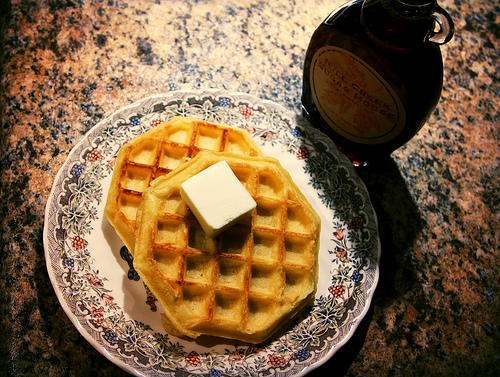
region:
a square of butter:
[182, 158, 254, 231]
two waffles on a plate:
[109, 118, 319, 345]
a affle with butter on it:
[138, 153, 317, 345]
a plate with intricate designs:
[45, 88, 379, 375]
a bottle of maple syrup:
[300, 1, 455, 166]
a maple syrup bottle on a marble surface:
[297, 4, 454, 157]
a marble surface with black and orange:
[3, 3, 496, 375]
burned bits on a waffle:
[115, 120, 226, 201]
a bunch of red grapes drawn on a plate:
[266, 351, 286, 366]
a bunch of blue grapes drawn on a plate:
[101, 325, 118, 346]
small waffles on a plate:
[37, 39, 439, 354]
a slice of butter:
[76, 109, 454, 375]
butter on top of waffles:
[46, 93, 468, 371]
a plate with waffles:
[30, 58, 452, 312]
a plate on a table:
[50, 64, 450, 351]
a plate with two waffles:
[54, 87, 307, 354]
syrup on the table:
[269, 16, 496, 218]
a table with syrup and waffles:
[2, 8, 492, 372]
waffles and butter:
[47, 81, 387, 361]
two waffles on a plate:
[107, 118, 329, 333]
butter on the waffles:
[178, 157, 261, 233]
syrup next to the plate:
[297, 1, 464, 155]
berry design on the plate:
[330, 212, 367, 303]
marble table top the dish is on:
[421, 183, 474, 290]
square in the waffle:
[212, 255, 249, 292]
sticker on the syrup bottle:
[303, 42, 411, 150]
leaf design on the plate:
[142, 326, 172, 360]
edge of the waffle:
[260, 155, 285, 175]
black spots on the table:
[122, 33, 170, 71]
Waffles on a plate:
[98, 116, 320, 350]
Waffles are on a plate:
[106, 116, 320, 341]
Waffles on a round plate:
[107, 106, 328, 346]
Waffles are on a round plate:
[108, 114, 323, 348]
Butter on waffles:
[179, 159, 264, 236]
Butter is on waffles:
[174, 155, 268, 235]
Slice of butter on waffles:
[173, 156, 263, 236]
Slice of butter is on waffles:
[178, 157, 257, 232]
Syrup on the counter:
[297, 3, 458, 160]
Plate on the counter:
[38, 86, 383, 373]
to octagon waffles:
[110, 117, 314, 340]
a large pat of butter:
[186, 163, 253, 228]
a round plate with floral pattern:
[45, 93, 384, 374]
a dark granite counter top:
[9, 9, 494, 375]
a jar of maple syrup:
[307, 1, 453, 162]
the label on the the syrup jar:
[308, 47, 407, 145]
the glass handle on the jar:
[428, 13, 453, 45]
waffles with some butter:
[107, 125, 317, 338]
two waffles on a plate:
[43, 93, 388, 375]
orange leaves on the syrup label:
[318, 58, 379, 131]